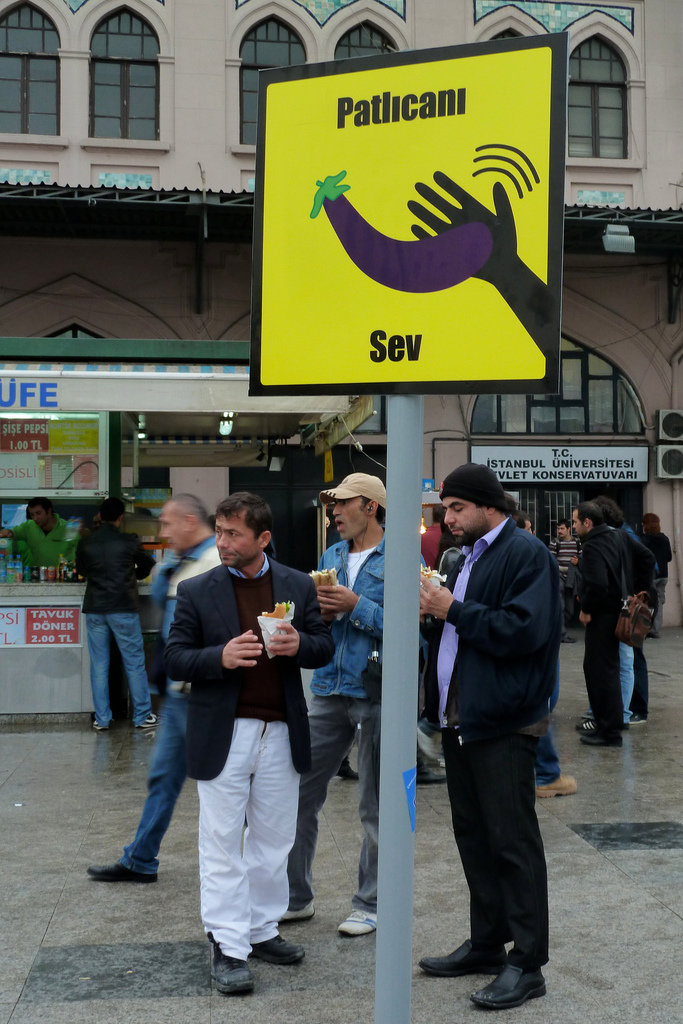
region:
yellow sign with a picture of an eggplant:
[252, 28, 562, 398]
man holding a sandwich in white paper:
[162, 490, 337, 995]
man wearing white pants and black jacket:
[160, 487, 336, 995]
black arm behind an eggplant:
[308, 162, 547, 363]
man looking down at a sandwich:
[415, 459, 565, 1008]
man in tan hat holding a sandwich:
[276, 470, 424, 939]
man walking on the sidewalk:
[85, 490, 219, 881]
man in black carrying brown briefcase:
[565, 500, 656, 749]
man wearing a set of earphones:
[273, 464, 432, 936]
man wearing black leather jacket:
[70, 492, 166, 733]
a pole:
[383, 648, 424, 752]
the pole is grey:
[373, 903, 415, 1014]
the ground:
[588, 920, 673, 1015]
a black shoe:
[476, 971, 547, 1007]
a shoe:
[468, 967, 543, 1010]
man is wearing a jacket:
[465, 650, 516, 717]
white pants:
[198, 786, 294, 957]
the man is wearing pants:
[200, 784, 285, 944]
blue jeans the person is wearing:
[87, 614, 153, 730]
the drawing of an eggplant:
[308, 168, 489, 289]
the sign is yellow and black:
[247, 28, 562, 393]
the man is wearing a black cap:
[417, 461, 562, 1007]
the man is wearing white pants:
[159, 487, 333, 996]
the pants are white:
[192, 716, 298, 956]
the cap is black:
[436, 460, 505, 505]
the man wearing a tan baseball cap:
[275, 469, 379, 933]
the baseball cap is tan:
[315, 471, 382, 506]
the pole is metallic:
[371, 396, 426, 1022]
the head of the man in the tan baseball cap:
[314, 471, 384, 543]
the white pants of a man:
[192, 715, 296, 958]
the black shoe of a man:
[208, 937, 246, 988]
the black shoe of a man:
[246, 928, 302, 961]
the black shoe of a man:
[583, 732, 623, 746]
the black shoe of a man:
[471, 957, 548, 1003]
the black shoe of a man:
[85, 858, 159, 883]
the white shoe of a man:
[336, 905, 372, 939]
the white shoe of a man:
[277, 901, 316, 918]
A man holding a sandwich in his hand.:
[246, 578, 298, 659]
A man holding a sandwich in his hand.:
[406, 537, 443, 618]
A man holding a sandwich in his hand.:
[308, 560, 344, 612]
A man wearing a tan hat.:
[316, 459, 385, 506]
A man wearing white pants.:
[178, 707, 311, 956]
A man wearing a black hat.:
[431, 449, 507, 509]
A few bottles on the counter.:
[5, 551, 25, 582]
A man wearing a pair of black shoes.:
[421, 928, 541, 1013]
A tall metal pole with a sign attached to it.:
[225, 54, 601, 1022]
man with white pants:
[153, 477, 344, 1022]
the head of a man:
[421, 467, 510, 541]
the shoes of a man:
[407, 904, 555, 1019]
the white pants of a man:
[199, 721, 304, 943]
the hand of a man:
[216, 616, 262, 686]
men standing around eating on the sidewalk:
[164, 470, 565, 1013]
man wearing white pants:
[162, 491, 337, 998]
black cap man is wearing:
[436, 461, 517, 521]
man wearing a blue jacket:
[285, 469, 427, 935]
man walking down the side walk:
[90, 495, 224, 885]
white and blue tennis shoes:
[338, 904, 384, 944]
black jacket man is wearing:
[160, 553, 345, 783]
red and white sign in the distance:
[0, 606, 88, 654]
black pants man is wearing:
[438, 723, 553, 970]